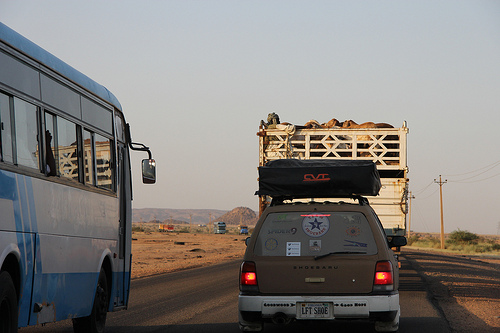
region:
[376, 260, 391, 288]
headlights on the car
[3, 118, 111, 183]
windows on the bus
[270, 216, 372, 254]
the back windshield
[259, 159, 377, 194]
luggage on the hood of the car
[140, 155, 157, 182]
the mirror on the bus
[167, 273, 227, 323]
the street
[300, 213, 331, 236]
a sticker on the windshield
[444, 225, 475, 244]
a green bush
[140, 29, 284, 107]
the sky is blue and clear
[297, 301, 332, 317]
a license plate on the car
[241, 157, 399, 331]
a sedan carrying a large black bag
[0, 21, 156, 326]
a long blue and white bus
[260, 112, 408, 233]
a truck carrying lots of animals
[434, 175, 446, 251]
a tall power pole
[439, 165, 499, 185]
long black power lines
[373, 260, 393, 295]
red brake lights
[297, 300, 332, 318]
a license plate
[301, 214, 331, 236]
a sticker with a star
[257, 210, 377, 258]
the back windshield of a car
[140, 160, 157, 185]
the rear view mirror of a bus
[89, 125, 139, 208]
Small window on a bus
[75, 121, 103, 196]
Small window on a bus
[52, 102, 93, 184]
Small window on a bus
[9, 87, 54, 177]
Small window on a bus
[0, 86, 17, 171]
Small window on a bus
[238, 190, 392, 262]
Small window on a car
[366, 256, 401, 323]
Red tail light of a car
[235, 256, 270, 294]
Red tail light of a car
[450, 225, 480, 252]
Patch of green grass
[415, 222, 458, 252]
Patch of green grass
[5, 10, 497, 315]
Traffic is traveling on a highway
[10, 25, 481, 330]
Vehicles are moving down the freeway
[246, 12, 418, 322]
A car is following a big truck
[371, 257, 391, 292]
The tail light of the car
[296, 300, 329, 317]
The license plate of a car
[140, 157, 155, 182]
The rear view mirror of a bus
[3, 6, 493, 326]
The cars are traveling in good weather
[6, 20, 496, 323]
The drivers are enjoying good road conditions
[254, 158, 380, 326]
The car has something attached to the roof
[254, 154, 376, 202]
A rack on the top of the truck.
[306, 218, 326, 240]
A star on back of truck.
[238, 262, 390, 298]
Rear lights on the truck.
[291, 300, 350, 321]
A white license plate on the truck.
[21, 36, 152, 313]
A bus on the street.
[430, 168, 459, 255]
Pole on the side of road.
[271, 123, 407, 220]
A white truck in front of vehicle.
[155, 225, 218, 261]
Dirt in the desert.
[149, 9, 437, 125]
The sky is blue.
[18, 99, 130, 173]
Windows on the bus.